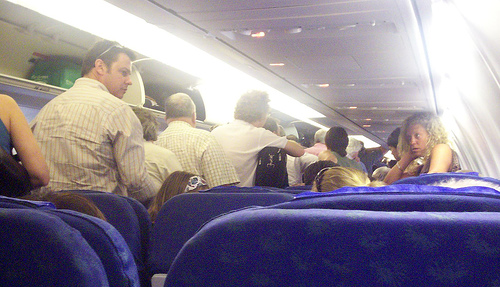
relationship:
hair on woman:
[397, 108, 445, 171] [383, 110, 460, 185]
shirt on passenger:
[153, 121, 238, 191] [148, 91, 241, 189]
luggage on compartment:
[28, 51, 83, 90] [8, 13, 53, 95]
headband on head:
[317, 159, 334, 191] [309, 162, 384, 190]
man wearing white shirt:
[205, 88, 303, 186] [209, 118, 289, 191]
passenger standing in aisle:
[148, 91, 238, 186] [113, 141, 377, 285]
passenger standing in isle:
[148, 91, 241, 189] [3, 121, 378, 251]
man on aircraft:
[30, 39, 165, 210] [0, 0, 498, 286]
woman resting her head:
[380, 109, 461, 185] [390, 108, 449, 158]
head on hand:
[390, 108, 449, 158] [393, 147, 416, 163]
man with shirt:
[30, 30, 169, 213] [30, 81, 164, 197]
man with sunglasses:
[30, 30, 169, 213] [97, 41, 128, 56]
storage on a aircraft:
[306, 12, 448, 126] [0, 0, 498, 286]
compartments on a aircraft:
[152, 7, 458, 152] [0, 0, 498, 286]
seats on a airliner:
[2, 170, 498, 285] [6, 2, 496, 283]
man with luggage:
[209, 94, 320, 198] [237, 139, 302, 191]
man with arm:
[209, 94, 320, 198] [253, 123, 306, 159]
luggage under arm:
[237, 139, 302, 191] [253, 123, 306, 159]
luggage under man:
[237, 139, 302, 191] [209, 94, 320, 198]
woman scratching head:
[380, 109, 461, 185] [402, 108, 443, 155]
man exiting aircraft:
[205, 88, 303, 186] [7, 8, 494, 281]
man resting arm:
[205, 88, 303, 186] [257, 124, 313, 163]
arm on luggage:
[257, 124, 313, 163] [237, 139, 302, 191]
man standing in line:
[30, 39, 165, 210] [3, 39, 366, 184]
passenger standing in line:
[148, 91, 241, 189] [3, 39, 366, 184]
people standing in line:
[131, 104, 179, 189] [3, 39, 366, 184]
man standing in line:
[205, 88, 303, 186] [3, 39, 366, 184]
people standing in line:
[253, 116, 287, 186] [3, 39, 366, 184]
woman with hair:
[380, 104, 470, 188] [397, 108, 445, 171]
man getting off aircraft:
[30, 39, 165, 210] [0, 0, 498, 286]